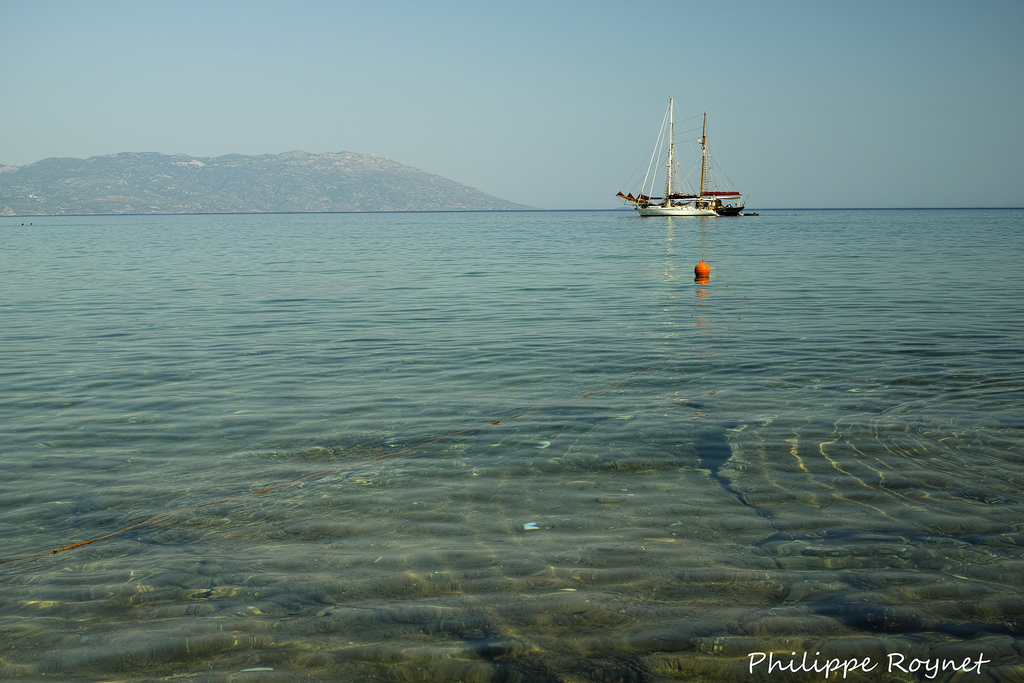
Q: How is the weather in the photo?
A: It is clear.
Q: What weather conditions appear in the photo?
A: It is clear.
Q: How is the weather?
A: It is clear.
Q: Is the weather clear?
A: Yes, it is clear.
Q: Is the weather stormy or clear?
A: It is clear.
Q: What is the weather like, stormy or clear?
A: It is clear.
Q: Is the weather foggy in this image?
A: No, it is clear.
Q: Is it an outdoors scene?
A: Yes, it is outdoors.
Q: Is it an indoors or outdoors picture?
A: It is outdoors.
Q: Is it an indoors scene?
A: No, it is outdoors.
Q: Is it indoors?
A: No, it is outdoors.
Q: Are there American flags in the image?
A: No, there are no American flags.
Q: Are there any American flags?
A: No, there are no American flags.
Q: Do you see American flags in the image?
A: No, there are no American flags.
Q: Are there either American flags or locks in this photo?
A: No, there are no American flags or locks.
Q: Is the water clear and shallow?
A: Yes, the water is clear and shallow.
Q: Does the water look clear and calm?
A: Yes, the water is clear and calm.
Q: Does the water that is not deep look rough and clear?
A: No, the water is clear but calm.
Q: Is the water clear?
A: Yes, the water is clear.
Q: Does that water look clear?
A: Yes, the water is clear.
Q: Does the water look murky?
A: No, the water is clear.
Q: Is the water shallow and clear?
A: Yes, the water is shallow and clear.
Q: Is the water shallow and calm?
A: Yes, the water is shallow and calm.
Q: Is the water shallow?
A: Yes, the water is shallow.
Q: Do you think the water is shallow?
A: Yes, the water is shallow.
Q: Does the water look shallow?
A: Yes, the water is shallow.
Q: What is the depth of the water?
A: The water is shallow.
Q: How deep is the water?
A: The water is shallow.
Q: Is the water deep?
A: No, the water is shallow.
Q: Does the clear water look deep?
A: No, the water is shallow.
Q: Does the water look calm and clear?
A: Yes, the water is calm and clear.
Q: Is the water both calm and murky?
A: No, the water is calm but clear.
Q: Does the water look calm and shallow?
A: Yes, the water is calm and shallow.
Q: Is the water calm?
A: Yes, the water is calm.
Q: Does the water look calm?
A: Yes, the water is calm.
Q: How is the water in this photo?
A: The water is calm.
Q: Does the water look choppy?
A: No, the water is calm.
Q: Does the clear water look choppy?
A: No, the water is calm.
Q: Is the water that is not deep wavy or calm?
A: The water is calm.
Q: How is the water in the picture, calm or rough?
A: The water is calm.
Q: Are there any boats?
A: Yes, there is a boat.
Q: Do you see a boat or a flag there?
A: Yes, there is a boat.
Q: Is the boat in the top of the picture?
A: Yes, the boat is in the top of the image.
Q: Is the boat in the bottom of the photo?
A: No, the boat is in the top of the image.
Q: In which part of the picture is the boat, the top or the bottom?
A: The boat is in the top of the image.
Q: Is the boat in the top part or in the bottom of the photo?
A: The boat is in the top of the image.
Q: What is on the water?
A: The boat is on the water.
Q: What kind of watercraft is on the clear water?
A: The watercraft is a boat.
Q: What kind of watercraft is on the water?
A: The watercraft is a boat.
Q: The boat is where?
A: The boat is on the water.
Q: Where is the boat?
A: The boat is on the water.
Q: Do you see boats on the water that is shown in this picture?
A: Yes, there is a boat on the water.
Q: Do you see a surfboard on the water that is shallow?
A: No, there is a boat on the water.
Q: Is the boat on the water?
A: Yes, the boat is on the water.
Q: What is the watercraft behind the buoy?
A: The watercraft is a boat.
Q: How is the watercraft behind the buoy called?
A: The watercraft is a boat.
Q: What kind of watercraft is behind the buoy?
A: The watercraft is a boat.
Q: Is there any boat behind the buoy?
A: Yes, there is a boat behind the buoy.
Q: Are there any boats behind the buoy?
A: Yes, there is a boat behind the buoy.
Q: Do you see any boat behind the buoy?
A: Yes, there is a boat behind the buoy.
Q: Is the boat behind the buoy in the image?
A: Yes, the boat is behind the buoy.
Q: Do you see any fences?
A: No, there are no fences.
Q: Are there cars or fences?
A: No, there are no fences or cars.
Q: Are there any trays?
A: No, there are no trays.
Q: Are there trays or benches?
A: No, there are no trays or benches.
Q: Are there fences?
A: No, there are no fences.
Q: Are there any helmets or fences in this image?
A: No, there are no fences or helmets.